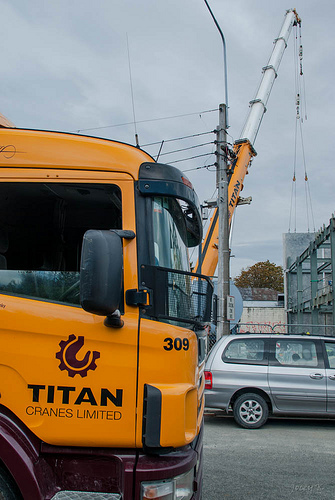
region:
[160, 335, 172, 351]
The number 3 on the truck.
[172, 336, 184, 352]
The number 0 on the truck.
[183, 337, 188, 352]
The number 9 on the truck.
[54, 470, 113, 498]
The step to enter the truck.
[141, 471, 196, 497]
The front headlight of the truck.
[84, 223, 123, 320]
The side mirror of the truck.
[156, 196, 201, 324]
The front window of the truck.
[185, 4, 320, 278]
The crane behind the truck.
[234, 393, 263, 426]
The back tire of the van.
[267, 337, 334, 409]
The side doors of the van.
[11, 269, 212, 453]
This is a bus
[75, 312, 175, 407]
The bus is yellow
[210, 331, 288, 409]
This is a car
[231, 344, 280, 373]
This is a window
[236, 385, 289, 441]
This is a window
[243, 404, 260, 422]
this is a wheel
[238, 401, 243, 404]
This is a tire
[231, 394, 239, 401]
The tire is black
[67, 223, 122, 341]
This is a mirror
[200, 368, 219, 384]
The light is red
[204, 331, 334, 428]
A car in the street.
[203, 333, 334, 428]
A car parked in the street.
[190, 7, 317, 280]
A crane on a truck.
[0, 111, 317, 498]
A yellow crane truck.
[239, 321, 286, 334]
Graffiti on a wall.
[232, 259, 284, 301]
A tree over a wall.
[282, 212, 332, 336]
A building being built.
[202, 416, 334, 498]
An asphalt paved road.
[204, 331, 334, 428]
A gray car on the street.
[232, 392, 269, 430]
A tire on a car.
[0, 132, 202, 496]
the truck is yellow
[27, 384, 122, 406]
the truck says titan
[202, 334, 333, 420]
the van is silver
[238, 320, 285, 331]
the wall has grafiti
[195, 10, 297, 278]
the crane is yellow and white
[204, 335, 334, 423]
the van is parked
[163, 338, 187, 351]
the truck has the number 309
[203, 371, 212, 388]
the tail light is red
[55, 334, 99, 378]
the truck has a logo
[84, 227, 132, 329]
the side mirror is black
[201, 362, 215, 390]
a taillight on the back of a car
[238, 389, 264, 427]
a tire on a car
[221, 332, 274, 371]
a window in the back of a car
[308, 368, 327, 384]
a doorhandle on the car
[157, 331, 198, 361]
a number on the side of the truck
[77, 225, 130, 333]
a mirror on the truck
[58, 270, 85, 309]
a stering wheel on the inside of the truck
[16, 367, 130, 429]
a name on the side of the truck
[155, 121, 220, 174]
powerlines coming off a pole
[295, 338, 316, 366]
seats in a car